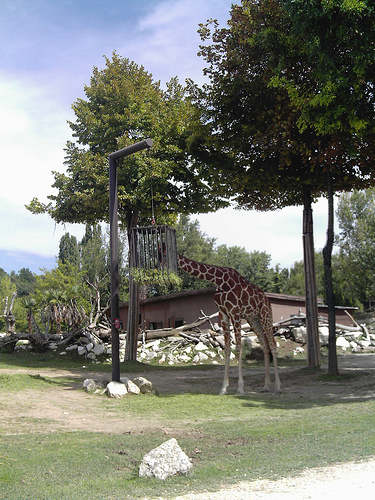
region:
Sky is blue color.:
[16, 14, 69, 74]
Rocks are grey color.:
[96, 330, 232, 362]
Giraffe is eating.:
[174, 258, 289, 398]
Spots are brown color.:
[225, 284, 259, 318]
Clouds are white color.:
[12, 118, 57, 190]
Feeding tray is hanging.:
[117, 205, 189, 288]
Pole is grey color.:
[100, 142, 187, 364]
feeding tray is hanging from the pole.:
[93, 141, 181, 377]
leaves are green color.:
[90, 112, 330, 204]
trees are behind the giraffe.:
[47, 120, 337, 344]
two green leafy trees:
[39, 2, 373, 213]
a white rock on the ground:
[137, 434, 193, 485]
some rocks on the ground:
[81, 371, 153, 397]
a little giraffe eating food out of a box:
[150, 245, 284, 393]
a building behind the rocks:
[107, 286, 357, 332]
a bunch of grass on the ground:
[6, 375, 366, 498]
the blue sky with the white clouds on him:
[2, 1, 234, 181]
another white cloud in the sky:
[208, 209, 303, 263]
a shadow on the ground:
[218, 362, 369, 411]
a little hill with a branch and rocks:
[139, 322, 220, 364]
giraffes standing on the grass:
[143, 224, 294, 404]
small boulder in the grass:
[128, 433, 198, 490]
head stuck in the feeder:
[134, 239, 200, 290]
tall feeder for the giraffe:
[96, 141, 203, 400]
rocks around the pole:
[83, 365, 158, 400]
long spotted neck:
[177, 249, 224, 283]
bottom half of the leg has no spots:
[234, 352, 248, 392]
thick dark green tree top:
[212, 0, 372, 212]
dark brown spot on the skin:
[223, 300, 233, 312]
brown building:
[108, 278, 325, 336]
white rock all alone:
[138, 436, 196, 484]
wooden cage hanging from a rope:
[128, 223, 183, 289]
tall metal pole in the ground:
[105, 135, 158, 396]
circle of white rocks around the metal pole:
[81, 371, 157, 403]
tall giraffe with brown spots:
[147, 240, 284, 395]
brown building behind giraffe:
[101, 276, 366, 362]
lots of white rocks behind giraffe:
[78, 330, 315, 368]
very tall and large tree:
[200, 19, 374, 384]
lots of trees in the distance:
[3, 227, 372, 329]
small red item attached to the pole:
[111, 316, 122, 331]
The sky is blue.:
[0, 0, 373, 276]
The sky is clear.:
[1, 0, 374, 281]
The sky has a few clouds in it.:
[0, 0, 374, 278]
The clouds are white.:
[0, 0, 372, 279]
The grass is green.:
[0, 347, 373, 496]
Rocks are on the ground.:
[139, 435, 193, 483]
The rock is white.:
[137, 436, 192, 477]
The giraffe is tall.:
[151, 237, 284, 392]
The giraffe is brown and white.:
[154, 241, 285, 396]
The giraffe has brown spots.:
[150, 240, 285, 396]